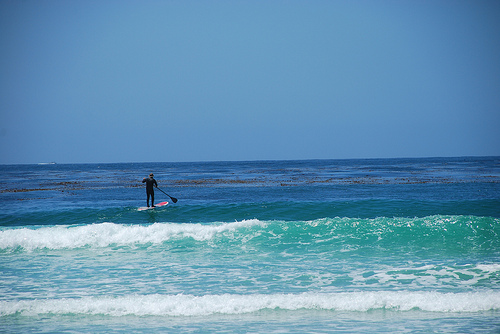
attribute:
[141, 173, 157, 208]
man — paddle boarding, alone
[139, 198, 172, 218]
board — white, red, partial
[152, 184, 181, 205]
paddle — black, partial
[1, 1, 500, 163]
sky — clear, blue, partial, bright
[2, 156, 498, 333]
ocean — blue, lapping on shore, partial, wave rippled, aqua colored, calm, green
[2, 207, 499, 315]
wave — crashing down, beginning to crest, small, swelling, partial, tipped, edged, coming forward, crashing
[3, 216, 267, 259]
sea foam — white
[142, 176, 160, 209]
wet suit — black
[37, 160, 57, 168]
boat — in the distance